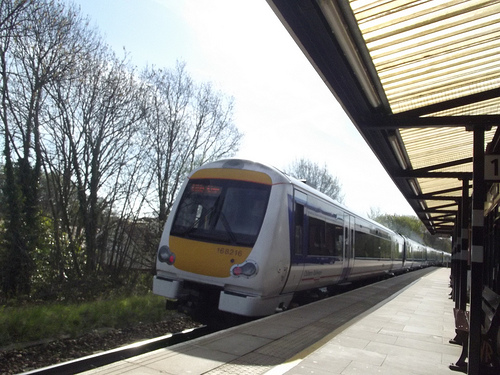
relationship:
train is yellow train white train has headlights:
[153, 156, 283, 310] [158, 243, 259, 281]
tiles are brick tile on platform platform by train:
[154, 264, 452, 374] [182, 263, 456, 374]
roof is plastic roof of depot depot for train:
[266, 0, 494, 341] [82, 0, 499, 373]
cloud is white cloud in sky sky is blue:
[132, 4, 336, 167] [3, 1, 412, 222]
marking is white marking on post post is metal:
[472, 209, 485, 227] [466, 127, 484, 371]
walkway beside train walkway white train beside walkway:
[77, 260, 440, 374] [150, 158, 449, 313]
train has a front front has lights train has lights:
[153, 156, 283, 310] [158, 243, 259, 281]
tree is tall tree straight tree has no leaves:
[24, 0, 94, 282] [62, 57, 123, 274]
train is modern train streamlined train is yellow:
[150, 158, 449, 313] [153, 156, 283, 310]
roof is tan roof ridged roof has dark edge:
[266, 0, 494, 341] [267, 0, 439, 235]